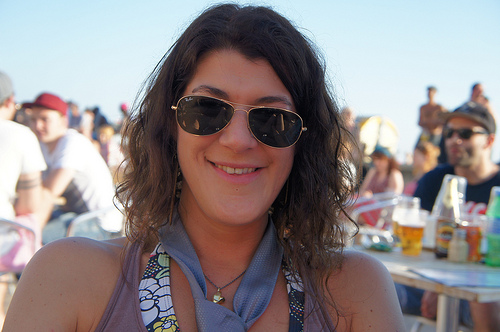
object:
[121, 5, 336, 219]
head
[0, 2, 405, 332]
woman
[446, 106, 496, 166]
head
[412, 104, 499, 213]
person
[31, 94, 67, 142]
head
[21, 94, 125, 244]
person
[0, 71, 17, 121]
head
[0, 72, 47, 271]
person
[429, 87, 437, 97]
head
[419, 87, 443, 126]
person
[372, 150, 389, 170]
head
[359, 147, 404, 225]
person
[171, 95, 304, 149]
sunglasses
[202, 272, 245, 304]
necklace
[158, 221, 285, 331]
tie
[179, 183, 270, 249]
neck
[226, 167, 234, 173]
tooth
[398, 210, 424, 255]
cup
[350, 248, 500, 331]
table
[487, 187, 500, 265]
bottle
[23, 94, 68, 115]
cap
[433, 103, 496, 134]
cap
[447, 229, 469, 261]
condiment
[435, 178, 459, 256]
bottle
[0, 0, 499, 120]
sky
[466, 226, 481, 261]
drink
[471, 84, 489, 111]
person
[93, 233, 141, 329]
strap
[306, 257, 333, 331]
top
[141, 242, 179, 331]
swimsuit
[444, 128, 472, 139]
sunglasses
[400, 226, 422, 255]
beer